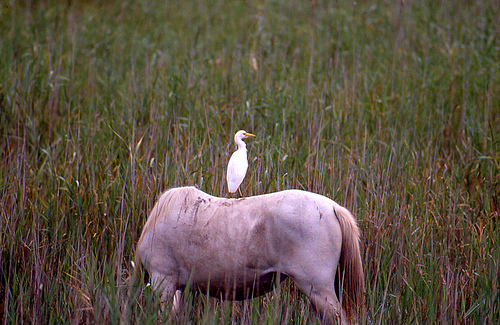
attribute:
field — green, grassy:
[3, 5, 498, 320]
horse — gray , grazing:
[118, 186, 367, 323]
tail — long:
[332, 207, 369, 322]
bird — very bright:
[225, 129, 257, 197]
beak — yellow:
[242, 132, 256, 137]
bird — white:
[224, 121, 257, 203]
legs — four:
[148, 275, 346, 322]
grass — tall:
[2, 2, 499, 128]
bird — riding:
[224, 120, 262, 205]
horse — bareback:
[138, 178, 363, 323]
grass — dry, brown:
[126, 16, 488, 199]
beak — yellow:
[242, 130, 254, 136]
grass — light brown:
[305, 31, 415, 117]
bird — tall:
[219, 127, 260, 197]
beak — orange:
[244, 129, 256, 136]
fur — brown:
[331, 204, 370, 315]